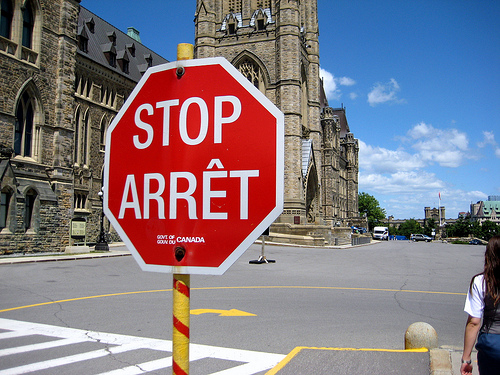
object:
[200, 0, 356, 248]
building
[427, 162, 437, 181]
ground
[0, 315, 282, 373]
paint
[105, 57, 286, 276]
board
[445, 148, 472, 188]
ground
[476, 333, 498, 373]
pants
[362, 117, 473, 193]
cloud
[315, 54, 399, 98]
cloud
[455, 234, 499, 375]
person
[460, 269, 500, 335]
white shirt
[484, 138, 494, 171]
clouds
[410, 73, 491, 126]
sky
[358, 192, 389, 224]
trees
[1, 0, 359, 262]
church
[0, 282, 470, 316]
line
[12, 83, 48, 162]
window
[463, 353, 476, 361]
silver band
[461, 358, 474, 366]
wrist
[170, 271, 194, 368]
red stripes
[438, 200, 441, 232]
pole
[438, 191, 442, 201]
flag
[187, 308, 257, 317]
arrow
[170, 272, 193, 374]
pole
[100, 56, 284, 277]
sign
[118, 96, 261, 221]
lettering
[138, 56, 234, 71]
border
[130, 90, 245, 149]
stop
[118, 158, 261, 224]
arrêt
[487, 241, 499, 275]
hair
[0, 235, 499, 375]
pavement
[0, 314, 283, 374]
lines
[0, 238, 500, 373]
road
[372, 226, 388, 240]
bus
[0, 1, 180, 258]
building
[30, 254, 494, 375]
distance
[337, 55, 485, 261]
part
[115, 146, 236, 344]
part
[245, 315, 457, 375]
edge